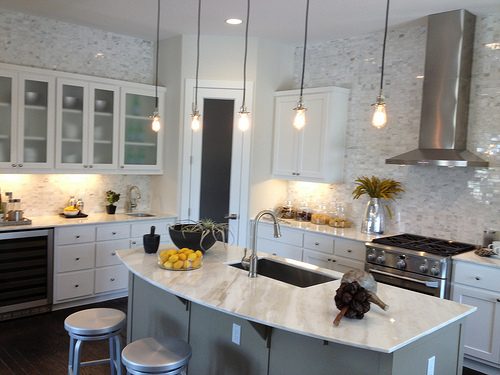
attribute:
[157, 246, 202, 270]
lemons — yellow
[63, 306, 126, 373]
stool — silver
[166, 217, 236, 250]
plant — small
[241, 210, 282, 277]
faucet — silver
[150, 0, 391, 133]
lights — hanging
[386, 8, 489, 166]
exhaust — silver, stainless steel, metal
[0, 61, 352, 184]
cupboards — white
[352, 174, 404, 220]
plant — green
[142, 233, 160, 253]
bowl — black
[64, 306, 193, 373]
stools — silver, round, grey, metal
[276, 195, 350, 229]
canisters — glass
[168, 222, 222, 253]
bowl — large, dark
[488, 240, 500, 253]
cup — white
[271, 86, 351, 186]
cabinet — white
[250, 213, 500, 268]
countertop — marbled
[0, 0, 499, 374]
kitchen — white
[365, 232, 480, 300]
oven — stainless steel, modern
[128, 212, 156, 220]
sink — small